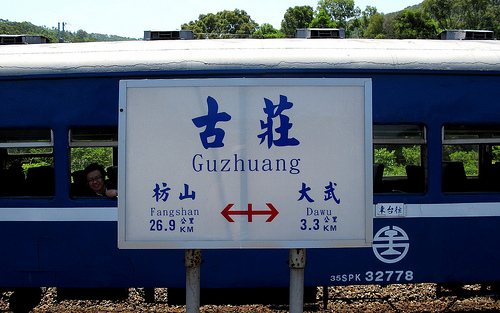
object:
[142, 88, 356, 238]
writing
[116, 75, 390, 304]
sign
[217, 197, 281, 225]
arrows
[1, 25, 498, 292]
train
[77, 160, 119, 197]
person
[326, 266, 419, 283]
number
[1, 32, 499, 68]
roof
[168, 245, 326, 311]
poles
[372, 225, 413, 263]
logo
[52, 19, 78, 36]
business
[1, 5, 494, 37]
trees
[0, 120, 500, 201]
windows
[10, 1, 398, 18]
sky